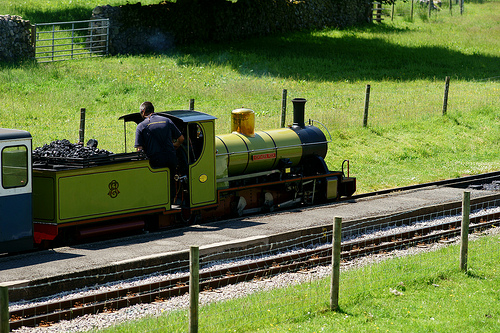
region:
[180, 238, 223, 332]
Post on a fence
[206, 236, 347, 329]
Wire on a fence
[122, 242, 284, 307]
Train track by grass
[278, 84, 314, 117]
Smoke stack on a train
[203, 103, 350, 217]
Engine on a train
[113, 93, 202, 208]
Man on a train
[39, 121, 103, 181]
Coal on a train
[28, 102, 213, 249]
Green train engine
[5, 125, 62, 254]
Blue and white train car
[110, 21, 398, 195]
Field by a train track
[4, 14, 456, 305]
yellow train on tracks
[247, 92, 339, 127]
black smoke stack on train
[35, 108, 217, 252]
second compartment on train fro coal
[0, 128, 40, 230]
third train car being pulled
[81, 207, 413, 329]
train tracks by train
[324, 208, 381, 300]
metal poles by track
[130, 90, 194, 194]
man standing on train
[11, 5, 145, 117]
metal gate in background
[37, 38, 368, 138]
grass field by train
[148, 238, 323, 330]
rocks on train tracks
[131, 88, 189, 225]
man on a mini train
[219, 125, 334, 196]
green train with red logo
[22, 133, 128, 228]
back of the train with coal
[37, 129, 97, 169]
coal for powering the train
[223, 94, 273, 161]
gold top to the train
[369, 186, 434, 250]
two sets of tracks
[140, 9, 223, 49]
wall made out of rocks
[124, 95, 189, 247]
man adding coal to train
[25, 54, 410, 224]
man on a green train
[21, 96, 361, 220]
mini green train with man driving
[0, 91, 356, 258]
Small locomotive going down track.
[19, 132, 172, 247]
Coal hopper car.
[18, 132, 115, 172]
Coal that is used to power small locomotive.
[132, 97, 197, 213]
Person operating small locomotive.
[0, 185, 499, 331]
Barbed wire fence.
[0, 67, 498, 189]
Barbed wire fence.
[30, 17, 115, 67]
Metal gate.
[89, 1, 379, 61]
Stone wall.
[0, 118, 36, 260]
Blue and white passenger car.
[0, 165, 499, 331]
A pair of train tracks.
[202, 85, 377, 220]
The train is for kids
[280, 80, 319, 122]
Small smokestack on front of train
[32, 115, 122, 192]
Huge amount of coal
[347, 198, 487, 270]
Track beside of train track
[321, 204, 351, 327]
Wooden fence post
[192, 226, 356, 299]
Barbed wire fence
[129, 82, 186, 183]
Man riding in small train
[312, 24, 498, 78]
The shadow is cast by the trees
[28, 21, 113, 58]
A silver gate is beside the fence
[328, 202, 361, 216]
Gravel beside the track